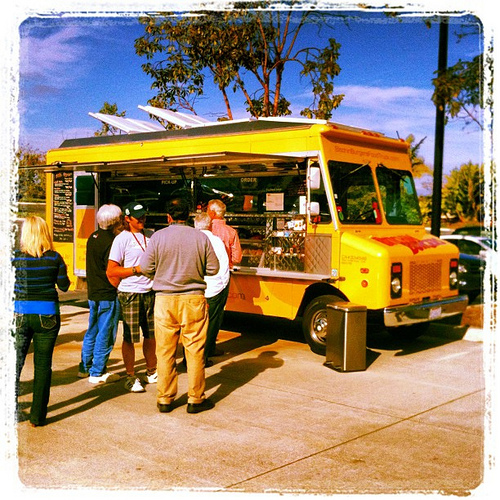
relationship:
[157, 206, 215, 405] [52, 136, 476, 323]
man standing near truck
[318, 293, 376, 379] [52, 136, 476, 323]
trash can by truck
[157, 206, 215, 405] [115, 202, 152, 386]
man talking to other man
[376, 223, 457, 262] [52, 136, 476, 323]
letters on truck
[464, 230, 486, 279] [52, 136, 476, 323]
cars behind truck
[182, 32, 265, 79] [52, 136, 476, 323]
tree behind truck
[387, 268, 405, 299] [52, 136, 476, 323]
headlight on truck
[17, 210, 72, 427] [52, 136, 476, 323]
woman near truck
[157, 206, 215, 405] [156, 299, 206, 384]
man yellow pants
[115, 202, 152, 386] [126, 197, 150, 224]
man wearing hat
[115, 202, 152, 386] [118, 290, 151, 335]
man wearing shorts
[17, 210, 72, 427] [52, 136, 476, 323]
woman waiting near truck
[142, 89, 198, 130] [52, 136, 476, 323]
vent on truck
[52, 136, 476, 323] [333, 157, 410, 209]
truck has windshield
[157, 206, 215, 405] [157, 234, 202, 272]
man wearing shirt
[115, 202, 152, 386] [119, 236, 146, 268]
man wearing shirt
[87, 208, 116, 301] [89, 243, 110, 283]
man in shirt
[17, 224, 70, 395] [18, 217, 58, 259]
woman has blonde hair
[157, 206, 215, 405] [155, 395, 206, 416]
man wearing shoes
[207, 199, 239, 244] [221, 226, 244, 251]
man wearing shirt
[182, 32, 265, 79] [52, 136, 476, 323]
tree above truck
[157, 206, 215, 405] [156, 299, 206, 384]
man wearing pants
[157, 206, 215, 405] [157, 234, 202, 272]
man wearing sweater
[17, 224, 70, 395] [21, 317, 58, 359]
woman wearing jeans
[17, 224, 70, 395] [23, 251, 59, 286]
woman wearing sweater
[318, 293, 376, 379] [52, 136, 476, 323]
trash can near truck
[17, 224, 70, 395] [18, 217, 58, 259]
woman with blonde hair